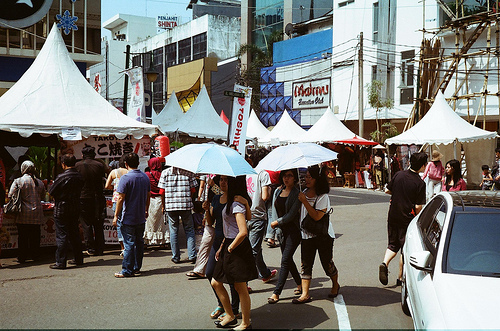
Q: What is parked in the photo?
A: A car.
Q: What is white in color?
A: The car.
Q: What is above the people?
A: Umbrellas.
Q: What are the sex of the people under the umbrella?
A: Female.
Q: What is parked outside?
A: Car.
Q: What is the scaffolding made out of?
A: Bamboo.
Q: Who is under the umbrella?
A: Two woman.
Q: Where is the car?
A: In street.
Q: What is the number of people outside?
A: Crowd.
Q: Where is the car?
A: In corner.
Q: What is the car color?
A: White.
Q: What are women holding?
A: Umbrellas.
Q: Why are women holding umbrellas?
A: To block the sun.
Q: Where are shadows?
A: On the pavement.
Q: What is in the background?
A: Buildings.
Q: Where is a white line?
A: On the ground.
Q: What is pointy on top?
A: Tents.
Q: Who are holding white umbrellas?
A: Women.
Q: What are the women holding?
A: Umbrellas.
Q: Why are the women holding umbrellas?
A: It is sunny outside.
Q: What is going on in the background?
A: A market.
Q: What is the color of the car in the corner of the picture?
A: White.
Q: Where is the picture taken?
A: In street.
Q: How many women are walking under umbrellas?
A: 4.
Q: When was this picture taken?
A: During the day.